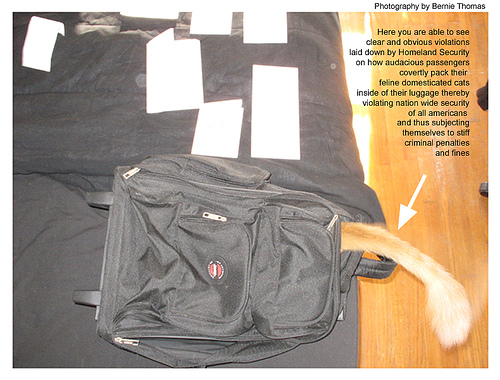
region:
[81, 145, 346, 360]
A black suit case.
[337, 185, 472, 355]
A cat's trail hanging out of the suitcase.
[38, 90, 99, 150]
The material is black.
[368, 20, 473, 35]
The text says here you are able to see.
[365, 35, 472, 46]
The text says clear and obvious violations.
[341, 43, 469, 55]
The text says laid down by Homeland Security.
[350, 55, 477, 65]
The text says on how audacious passengers.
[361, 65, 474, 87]
The text says convertly pack their feline domesticated cats.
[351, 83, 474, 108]
The text says inside their luggage thereby violation nation wide security.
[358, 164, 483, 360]
An arrow pointing to a cat tail.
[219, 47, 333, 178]
white envelope on black background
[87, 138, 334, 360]
black backpack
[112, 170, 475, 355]
black backpack with orange cat tail sticking out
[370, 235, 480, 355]
orange cat tail above wooden floor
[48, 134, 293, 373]
black backpack on black bed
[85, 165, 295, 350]
black backpack with silver zippers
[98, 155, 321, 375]
black backpack with red logo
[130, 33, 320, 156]
three white pieces of paper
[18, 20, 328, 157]
various pieces of paper on black blanket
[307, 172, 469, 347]
fluffy cat tail coming out of bag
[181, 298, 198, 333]
the bag is black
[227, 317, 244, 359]
the bag is black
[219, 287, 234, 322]
the bag is black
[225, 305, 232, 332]
the bag is black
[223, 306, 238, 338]
the bag is black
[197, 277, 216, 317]
the bag is black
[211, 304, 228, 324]
the bag is black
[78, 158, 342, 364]
a black and red bag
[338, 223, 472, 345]
the tail of an animal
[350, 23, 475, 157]
black text added to image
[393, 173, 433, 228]
a white arrow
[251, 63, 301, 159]
white block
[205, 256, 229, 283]
red logo on a bag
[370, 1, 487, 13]
photography credit written in black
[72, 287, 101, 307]
foot of a bag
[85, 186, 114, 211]
foot of a bag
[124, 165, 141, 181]
metal zipper on a bag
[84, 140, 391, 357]
a black backpack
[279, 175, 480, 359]
a cat tail in the bag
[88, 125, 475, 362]
an orange cat stuck in a backpack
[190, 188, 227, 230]
a silver zipper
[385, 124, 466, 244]
wood flooring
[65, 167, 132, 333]
black legs for the backpack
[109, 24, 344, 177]
white papers on the furniture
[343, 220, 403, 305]
handle of the backpack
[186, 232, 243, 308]
red logo on the backpack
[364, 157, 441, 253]
white arrow